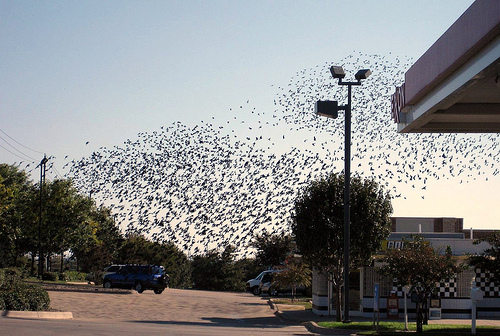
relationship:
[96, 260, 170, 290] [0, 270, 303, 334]
suv in parking lot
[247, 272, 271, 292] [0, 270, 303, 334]
van in parking lot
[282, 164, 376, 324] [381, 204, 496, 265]
tree next to building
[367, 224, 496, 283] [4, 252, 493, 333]
building in parking lot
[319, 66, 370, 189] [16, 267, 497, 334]
light in parking lot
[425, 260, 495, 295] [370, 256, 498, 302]
checks on building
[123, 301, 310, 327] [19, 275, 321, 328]
shadow on parking lot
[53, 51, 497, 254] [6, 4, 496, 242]
bird flock in sky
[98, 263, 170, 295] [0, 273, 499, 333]
suv in lot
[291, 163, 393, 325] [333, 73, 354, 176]
tree near pole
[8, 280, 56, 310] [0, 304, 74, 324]
bushes on median strip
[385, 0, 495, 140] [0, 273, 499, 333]
roof hanging over lot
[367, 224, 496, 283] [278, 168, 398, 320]
building behind tree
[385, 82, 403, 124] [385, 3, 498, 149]
letter on roof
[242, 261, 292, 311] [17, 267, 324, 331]
cars in parking lot